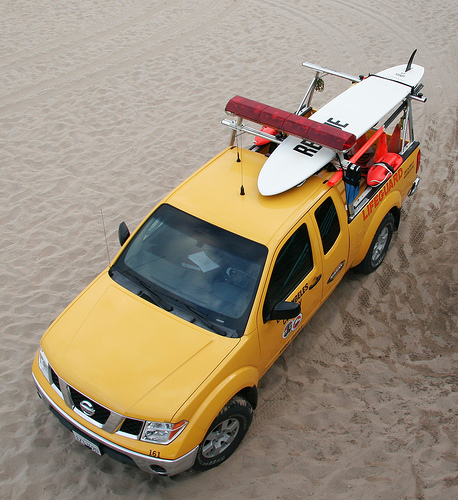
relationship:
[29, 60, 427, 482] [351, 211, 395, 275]
car has back tire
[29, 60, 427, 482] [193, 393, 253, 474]
car has front wheel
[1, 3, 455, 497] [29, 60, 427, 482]
sand has car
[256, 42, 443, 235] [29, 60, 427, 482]
surfboard on car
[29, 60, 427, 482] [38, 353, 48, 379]
car has headlight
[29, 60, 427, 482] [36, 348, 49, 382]
car has headlight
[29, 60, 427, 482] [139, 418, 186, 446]
car has headlight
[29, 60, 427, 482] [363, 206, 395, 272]
car has back tire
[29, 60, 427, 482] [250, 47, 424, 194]
car carrying surfboard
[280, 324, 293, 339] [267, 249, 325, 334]
emblem on truck door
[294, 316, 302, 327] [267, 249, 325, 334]
emblem on truck door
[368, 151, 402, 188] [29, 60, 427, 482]
saving device on car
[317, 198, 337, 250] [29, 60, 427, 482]
window of car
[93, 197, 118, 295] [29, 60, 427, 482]
antennae of car